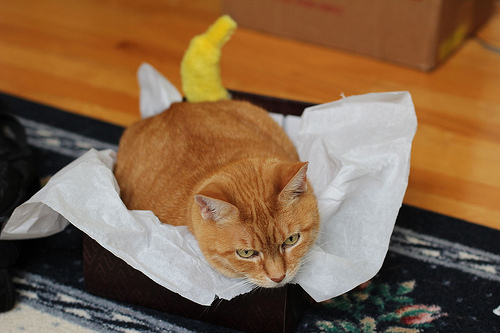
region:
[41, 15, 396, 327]
The cat is in a shoebox.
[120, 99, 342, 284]
The cat is brown.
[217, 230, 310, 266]
The cat's eyes are green.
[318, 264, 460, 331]
The rug has flowers.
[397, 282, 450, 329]
The flowers are pink.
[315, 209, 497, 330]
The rug is blue and white.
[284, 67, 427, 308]
The paper is white.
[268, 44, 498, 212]
The floor is wood.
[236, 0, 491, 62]
Box behind the rug.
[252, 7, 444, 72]
The box is cardboard.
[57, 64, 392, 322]
cat laying in a box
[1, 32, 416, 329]
cat laying on a white tissue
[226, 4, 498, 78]
cardboard box on the floor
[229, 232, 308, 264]
two bright green eyes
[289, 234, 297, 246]
black dot in the center of the eye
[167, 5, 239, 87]
top of a yellow stuffed toy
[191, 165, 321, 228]
two small, pointy ears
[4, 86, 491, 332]
dark blue rug on the floor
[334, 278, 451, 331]
flower design on the rug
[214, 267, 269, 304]
thin white whiskers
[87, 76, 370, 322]
A cat sitting in a shoebox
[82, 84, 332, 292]
A fat orange cat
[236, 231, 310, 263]
The cat has green eyes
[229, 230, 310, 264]
The cat's eyes are open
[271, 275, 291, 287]
The cat's nose is pink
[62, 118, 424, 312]
White paper beneath the cat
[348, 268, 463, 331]
A rug with a floral pattern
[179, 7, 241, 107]
A yellow plush banana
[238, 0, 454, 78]
A cardboard box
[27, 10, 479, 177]
A polished wooden floor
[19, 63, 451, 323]
a cat in a box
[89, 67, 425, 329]
a cat on a box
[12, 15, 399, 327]
a cat on tissue paper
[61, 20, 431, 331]
an orange cat on a box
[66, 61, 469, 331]
an orange cat in a box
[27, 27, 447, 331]
an orange cat on tissue paper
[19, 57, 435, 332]
a cat in a small box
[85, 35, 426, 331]
an orange cat in a small box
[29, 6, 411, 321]
a cat in white tissue paper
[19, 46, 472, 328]
an orange cat on white tissue paper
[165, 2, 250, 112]
a yellow cat toy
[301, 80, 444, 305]
white tissue paper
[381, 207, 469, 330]
a blue rug on the hardwood floor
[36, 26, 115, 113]
a light colored hardwood floor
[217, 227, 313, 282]
olive colored cats eyes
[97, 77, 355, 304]
an orange cat sitting on tissue paper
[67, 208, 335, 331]
a box of tissue paper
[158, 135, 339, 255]
cats ears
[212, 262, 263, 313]
white cat whiskers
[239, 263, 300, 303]
pink nose of a cat